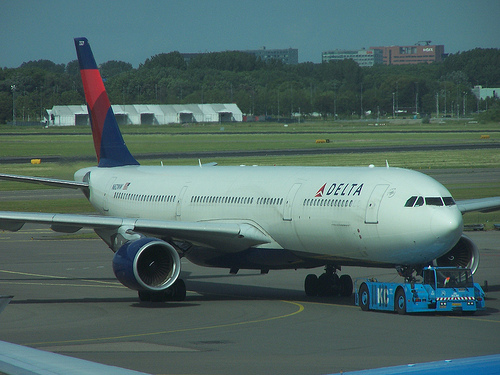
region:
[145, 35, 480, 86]
tall commercial buildings in the distance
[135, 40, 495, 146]
trees growing at the edge of the airport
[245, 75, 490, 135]
tall wire fencing in front of the trees at airport border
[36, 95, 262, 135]
flat grey building with different covered entry points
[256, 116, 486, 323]
blue service vehicle underneath airplane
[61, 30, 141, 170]
plane tail in red orange brown and blue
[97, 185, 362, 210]
row of passenger windows across the fuselage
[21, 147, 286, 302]
turbine engine under plane wing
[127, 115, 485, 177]
paths in airport separated by grass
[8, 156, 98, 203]
horizontal stabilizer at rear of plane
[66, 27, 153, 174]
tail of the plane is red and blue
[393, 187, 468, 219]
four windows in the front of the plane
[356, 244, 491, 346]
blue vehicle to push the plane out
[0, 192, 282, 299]
wing of the plane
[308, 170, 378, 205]
the word DELTA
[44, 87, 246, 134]
airplane hanger with five doors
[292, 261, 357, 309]
four wheels under the plane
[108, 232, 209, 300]
airplane engine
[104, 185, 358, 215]
passenger windows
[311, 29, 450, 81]
two buildings in the distance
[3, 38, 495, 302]
red white and maroon Delta plane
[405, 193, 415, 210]
wide front airplane window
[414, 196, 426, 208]
wide front airplane window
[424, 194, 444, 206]
wide front airplane window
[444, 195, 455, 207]
wide front airplane window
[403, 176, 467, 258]
wide front white airplane nose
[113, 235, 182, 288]
rounded blue airplane engine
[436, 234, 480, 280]
rounded blue airplane engine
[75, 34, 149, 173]
red blue and maroon airplane tail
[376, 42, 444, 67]
large brick building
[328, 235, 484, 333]
a tow truck for planes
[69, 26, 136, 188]
a red, orange and blue tail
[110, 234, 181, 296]
an engine shrouded in blue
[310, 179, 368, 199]
a name and a logo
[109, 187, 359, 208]
a row of passenger windows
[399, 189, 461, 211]
windows for the pilots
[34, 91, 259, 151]
a small hangar in the distance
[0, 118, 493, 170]
a runway at a big airport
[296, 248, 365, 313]
landing gear of a jet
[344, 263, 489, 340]
a light blue piece of equipment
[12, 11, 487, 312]
Airplane parked in service area.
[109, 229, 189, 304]
Huge engine under plane's wing.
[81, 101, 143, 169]
Blue and red tail on plane.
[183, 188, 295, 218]
Windows on side of plane.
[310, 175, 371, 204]
Plane's company name written in blue.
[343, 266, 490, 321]
Blue service truck in front of plane.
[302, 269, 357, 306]
Four wheels under plane.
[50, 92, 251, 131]
White building across from runway.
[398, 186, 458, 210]
Windows to plane's cockpit.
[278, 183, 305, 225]
Door leading into plane.